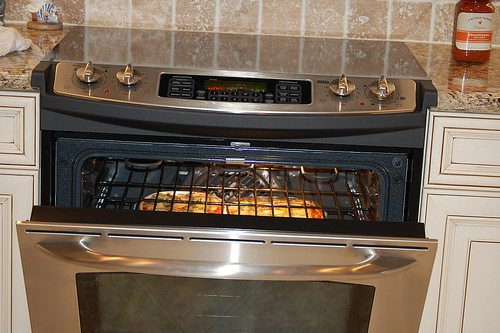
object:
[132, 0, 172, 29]
tile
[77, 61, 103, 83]
knob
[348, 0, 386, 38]
tile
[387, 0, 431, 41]
tile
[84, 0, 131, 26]
tile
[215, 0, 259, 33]
tile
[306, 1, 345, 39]
tile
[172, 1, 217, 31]
tile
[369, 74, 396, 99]
knob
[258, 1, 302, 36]
tile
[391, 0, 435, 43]
tile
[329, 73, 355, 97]
knob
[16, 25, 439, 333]
oven